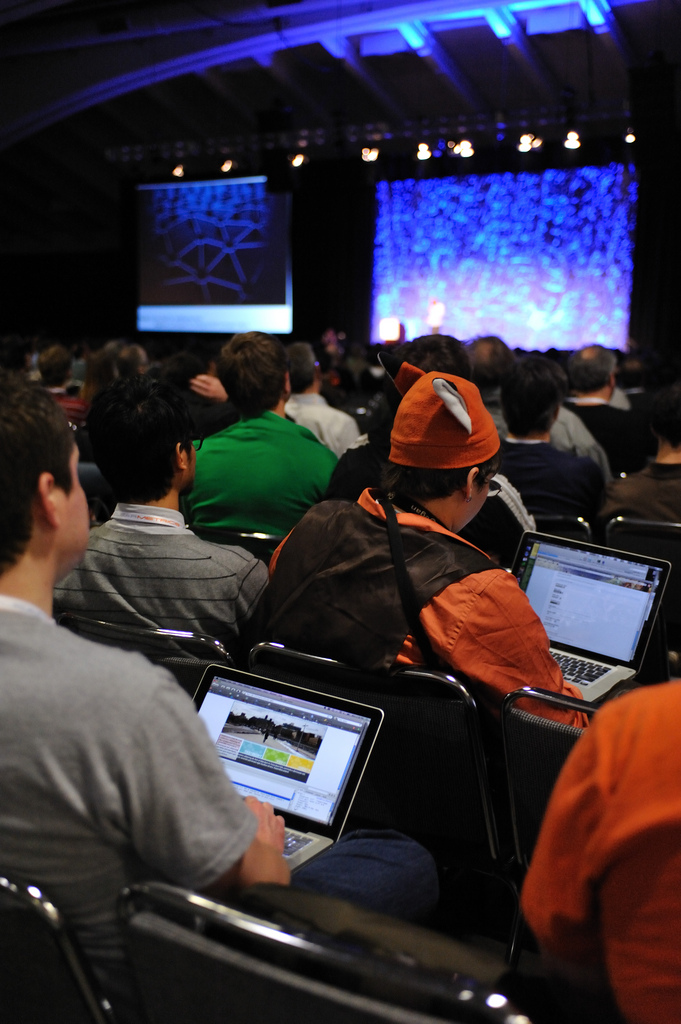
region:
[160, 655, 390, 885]
laptop in man's lap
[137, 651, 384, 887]
man's laptop is black and silver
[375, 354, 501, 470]
man's cap is orange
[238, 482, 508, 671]
man wearing a vest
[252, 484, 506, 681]
man's vest is black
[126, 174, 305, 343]
large screen on wall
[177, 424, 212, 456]
man wearing glasses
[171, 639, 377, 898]
THIS IS A LAPTOP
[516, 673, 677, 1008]
THE MAN IS WEARING AN ORANGE SHIRT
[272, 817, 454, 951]
THE MAN IS WEARING JEANS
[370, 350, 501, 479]
THE MAN'S HAT IS ORANGE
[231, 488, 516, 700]
THE MAN'S VEST IS BLACK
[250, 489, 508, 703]
THE MAN IS WEARING A VEST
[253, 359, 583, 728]
person sitting watching seminar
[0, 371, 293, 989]
person sitting watching seminar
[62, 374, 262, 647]
person sitting watching seminar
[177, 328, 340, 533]
person sitting watching seminar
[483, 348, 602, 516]
person sitting watching seminar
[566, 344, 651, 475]
person sitting watching seminar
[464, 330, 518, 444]
person sitting watching seminar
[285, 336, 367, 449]
person sitting watching seminar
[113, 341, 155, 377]
person sitting watching seminar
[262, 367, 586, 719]
person watching seminar presentation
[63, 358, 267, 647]
person watching seminar presentation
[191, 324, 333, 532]
person watching seminar presentation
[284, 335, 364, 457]
person watching seminar presentation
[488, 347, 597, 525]
person watching seminar presentation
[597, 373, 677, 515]
person watching seminar presentation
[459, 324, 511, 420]
person watching seminar presentation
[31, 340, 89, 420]
person watching seminar presentation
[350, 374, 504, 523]
the head of a man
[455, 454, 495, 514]
the ear of a man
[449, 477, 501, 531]
the cheek of a man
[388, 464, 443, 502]
the hair of a man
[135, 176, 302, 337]
large projector screen hanging from ceiling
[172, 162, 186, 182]
track light hanging from ceiling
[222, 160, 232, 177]
track light hanging from ceiling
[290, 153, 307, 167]
track light hanging from ceiling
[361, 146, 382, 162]
track light hanging from ceiling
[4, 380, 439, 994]
man sitting in a chair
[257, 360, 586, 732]
man wearing a brown and orange hat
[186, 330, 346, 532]
man wearing a green polo shirt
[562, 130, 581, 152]
track light hanging from ceiling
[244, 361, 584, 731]
person sitting in theatre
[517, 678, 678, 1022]
person sitting in theatre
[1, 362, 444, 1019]
person sitting in theatre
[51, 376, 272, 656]
person sitting in theatre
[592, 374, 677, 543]
person sitting in theatre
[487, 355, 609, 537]
person sitting in theatre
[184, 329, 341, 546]
person sitting in theatre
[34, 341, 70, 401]
person sitting in theatre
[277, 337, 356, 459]
person sitting in theatre